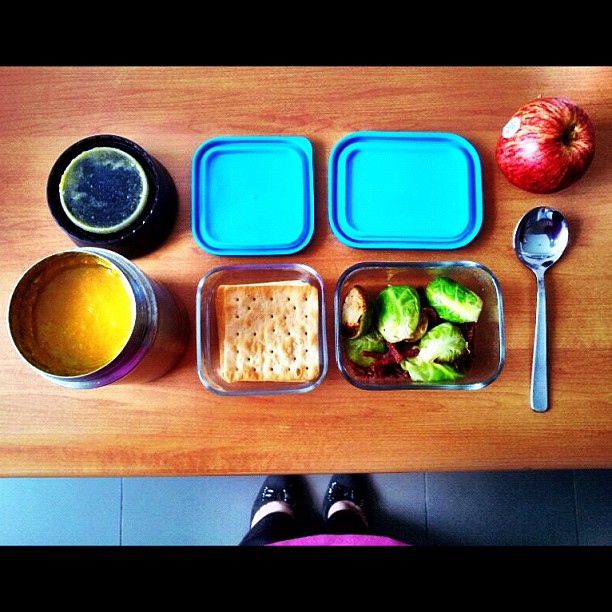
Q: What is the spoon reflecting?
A: The room.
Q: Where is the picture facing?
A: Downward.